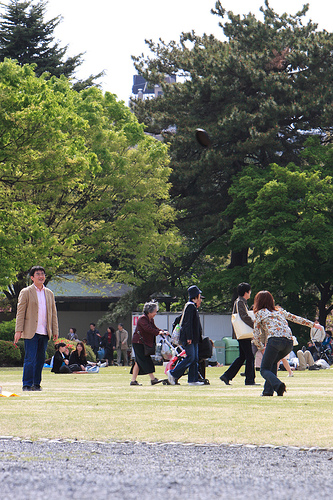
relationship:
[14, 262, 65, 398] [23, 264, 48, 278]
man has hair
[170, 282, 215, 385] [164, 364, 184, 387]
man wearing a shoe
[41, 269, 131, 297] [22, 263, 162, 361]
roof on building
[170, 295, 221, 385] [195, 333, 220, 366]
woman has a purse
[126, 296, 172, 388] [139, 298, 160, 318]
woman has hair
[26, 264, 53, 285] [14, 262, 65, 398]
head on man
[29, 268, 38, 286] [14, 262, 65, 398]
ear on man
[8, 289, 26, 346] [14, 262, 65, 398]
arm on man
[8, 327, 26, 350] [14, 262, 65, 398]
hand on man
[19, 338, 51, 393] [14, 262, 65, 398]
legs are on man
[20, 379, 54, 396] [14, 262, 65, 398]
feet are on man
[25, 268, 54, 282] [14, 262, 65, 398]
eyes are on man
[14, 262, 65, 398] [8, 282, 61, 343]
man wearing a jacket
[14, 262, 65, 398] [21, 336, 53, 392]
man wearing pants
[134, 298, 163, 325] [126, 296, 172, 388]
head on woman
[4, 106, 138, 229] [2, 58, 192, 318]
leaves are on tree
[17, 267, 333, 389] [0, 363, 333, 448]
people are on field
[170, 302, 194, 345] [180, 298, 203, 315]
bag on shoulder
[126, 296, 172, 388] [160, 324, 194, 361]
woman pushing a stroller handle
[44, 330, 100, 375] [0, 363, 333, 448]
people are on field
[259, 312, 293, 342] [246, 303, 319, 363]
print on shirt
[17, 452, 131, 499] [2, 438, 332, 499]
dirt on ground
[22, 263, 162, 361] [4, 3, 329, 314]
building behind trees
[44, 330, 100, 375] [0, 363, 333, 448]
people are in field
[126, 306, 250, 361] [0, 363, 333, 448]
truck by field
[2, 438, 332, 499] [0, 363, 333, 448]
ground by field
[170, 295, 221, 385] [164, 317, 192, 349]
woman has a bag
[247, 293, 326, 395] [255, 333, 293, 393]
woman wearing jeans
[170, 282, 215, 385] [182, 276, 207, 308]
man wearing a hat